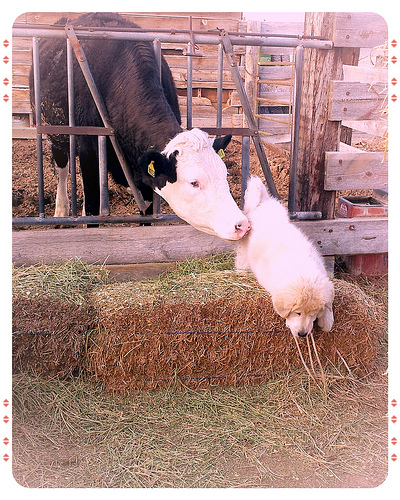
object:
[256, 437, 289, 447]
leaf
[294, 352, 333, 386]
rope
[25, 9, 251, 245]
cow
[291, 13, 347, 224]
wooden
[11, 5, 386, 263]
fence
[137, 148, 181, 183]
ears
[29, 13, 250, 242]
bull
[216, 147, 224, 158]
tags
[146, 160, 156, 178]
tags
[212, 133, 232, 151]
ear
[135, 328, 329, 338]
rope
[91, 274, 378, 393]
bale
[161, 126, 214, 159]
hair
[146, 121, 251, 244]
head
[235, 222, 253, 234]
ring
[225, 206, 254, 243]
nose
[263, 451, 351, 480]
dirt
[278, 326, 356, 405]
hay stick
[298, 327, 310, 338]
nose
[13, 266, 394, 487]
hay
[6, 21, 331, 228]
metal pen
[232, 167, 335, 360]
puppy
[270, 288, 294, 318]
ears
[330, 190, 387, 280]
container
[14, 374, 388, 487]
straw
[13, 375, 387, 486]
grass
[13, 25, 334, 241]
gate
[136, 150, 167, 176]
ear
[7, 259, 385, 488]
grain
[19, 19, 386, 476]
field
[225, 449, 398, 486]
area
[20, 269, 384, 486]
ground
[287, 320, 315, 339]
mouth